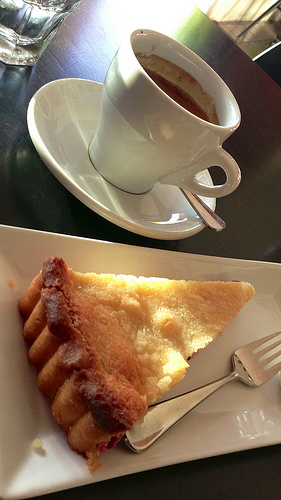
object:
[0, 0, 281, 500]
image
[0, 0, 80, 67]
glass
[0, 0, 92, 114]
corner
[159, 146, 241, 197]
handle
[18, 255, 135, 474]
crust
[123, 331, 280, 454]
fork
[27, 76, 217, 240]
plate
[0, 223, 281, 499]
plate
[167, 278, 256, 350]
piece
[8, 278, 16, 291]
crumbs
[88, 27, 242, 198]
cup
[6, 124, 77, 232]
reflection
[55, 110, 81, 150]
reflection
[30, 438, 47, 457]
crumb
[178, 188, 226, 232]
teaspoon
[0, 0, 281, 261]
table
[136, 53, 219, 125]
chocolate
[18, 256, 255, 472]
pie